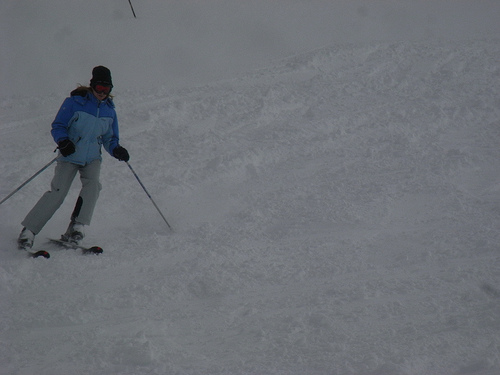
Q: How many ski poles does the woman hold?
A: Two.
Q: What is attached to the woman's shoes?
A: Skis.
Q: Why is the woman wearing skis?
A: She is skiing.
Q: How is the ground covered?
A: With snow.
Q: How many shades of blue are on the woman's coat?
A: Two.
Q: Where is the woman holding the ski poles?
A: In her hands.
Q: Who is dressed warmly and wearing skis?
A: The female skier.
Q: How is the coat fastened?
A: Fully zipped.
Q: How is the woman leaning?
A: To her left.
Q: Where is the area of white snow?
A: Next to the skier.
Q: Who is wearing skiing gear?
A: The woman.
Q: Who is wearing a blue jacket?
A: The woman.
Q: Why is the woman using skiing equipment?
A: To ski.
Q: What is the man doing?
A: Skiing.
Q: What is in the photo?
A: A man.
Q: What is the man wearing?
A: Clothes.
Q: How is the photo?
A: Clear.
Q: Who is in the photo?
A: A lady.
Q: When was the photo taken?
A: Daytime.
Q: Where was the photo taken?
A: On a ski slope.